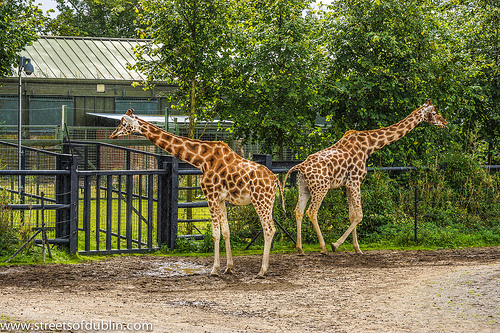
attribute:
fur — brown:
[161, 162, 326, 274]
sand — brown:
[216, 287, 381, 323]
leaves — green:
[206, 22, 440, 109]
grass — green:
[348, 191, 493, 263]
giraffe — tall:
[245, 74, 494, 279]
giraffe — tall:
[114, 105, 368, 325]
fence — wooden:
[48, 100, 438, 261]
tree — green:
[143, 13, 312, 163]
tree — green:
[197, 0, 333, 180]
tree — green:
[301, 0, 470, 176]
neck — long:
[138, 119, 209, 163]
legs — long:
[206, 201, 277, 279]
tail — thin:
[281, 165, 299, 196]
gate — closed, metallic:
[77, 165, 171, 252]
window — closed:
[113, 98, 163, 120]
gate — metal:
[75, 170, 169, 258]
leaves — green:
[177, 19, 220, 69]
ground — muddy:
[0, 247, 496, 331]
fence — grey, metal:
[1, 142, 497, 253]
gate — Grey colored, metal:
[3, 136, 498, 254]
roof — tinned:
[4, 39, 246, 81]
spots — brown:
[328, 160, 346, 180]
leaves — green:
[182, 36, 269, 93]